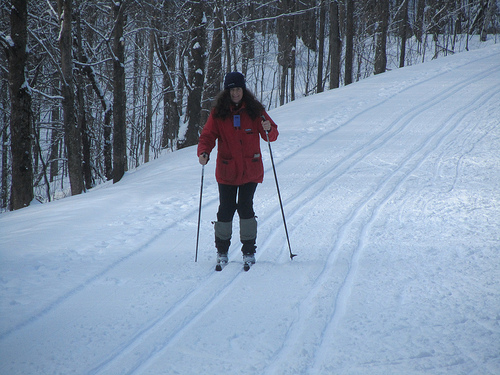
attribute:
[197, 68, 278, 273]
woman — skiing, standing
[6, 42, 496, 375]
snow — white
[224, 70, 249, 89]
hat — black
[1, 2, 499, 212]
trees — brown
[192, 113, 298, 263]
ski poles — black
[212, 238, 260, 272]
boots — white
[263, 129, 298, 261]
ski pole — black